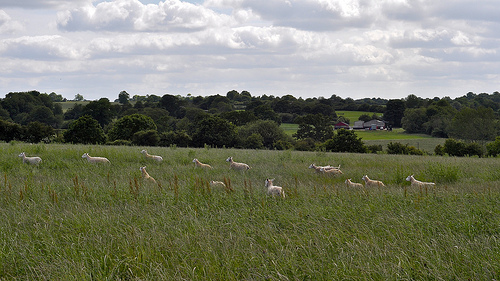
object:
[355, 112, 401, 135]
barn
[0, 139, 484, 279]
field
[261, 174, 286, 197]
sheep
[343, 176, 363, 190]
sheep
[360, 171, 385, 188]
sheep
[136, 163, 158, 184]
sheep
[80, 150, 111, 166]
sheep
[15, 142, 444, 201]
sheep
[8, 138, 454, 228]
flock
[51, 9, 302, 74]
sky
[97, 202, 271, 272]
grass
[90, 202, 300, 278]
grass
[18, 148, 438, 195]
grass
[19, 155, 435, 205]
sheep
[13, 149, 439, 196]
sheep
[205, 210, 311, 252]
grass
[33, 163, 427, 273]
field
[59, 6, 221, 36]
clouds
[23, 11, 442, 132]
sky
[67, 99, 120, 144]
tree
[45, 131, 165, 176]
grass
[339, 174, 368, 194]
sheep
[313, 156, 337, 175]
sheep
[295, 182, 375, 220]
grass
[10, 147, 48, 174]
sheep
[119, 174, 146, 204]
weeds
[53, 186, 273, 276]
grass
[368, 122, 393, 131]
cars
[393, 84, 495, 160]
trees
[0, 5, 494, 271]
outside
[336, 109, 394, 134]
house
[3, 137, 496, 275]
pasture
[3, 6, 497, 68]
clouds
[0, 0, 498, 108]
sky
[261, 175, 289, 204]
sheep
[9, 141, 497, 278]
grass